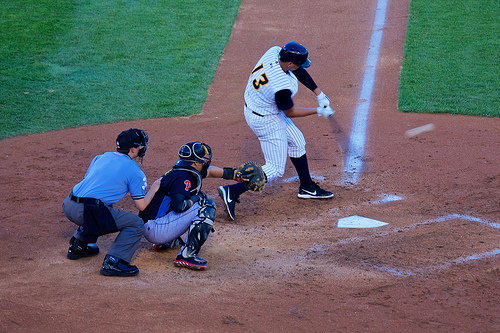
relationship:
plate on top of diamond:
[337, 211, 381, 232] [351, 15, 499, 215]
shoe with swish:
[298, 183, 332, 202] [303, 188, 319, 197]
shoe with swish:
[219, 181, 236, 218] [227, 186, 232, 203]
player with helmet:
[235, 32, 323, 203] [278, 39, 311, 68]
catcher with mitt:
[144, 141, 217, 266] [232, 161, 268, 190]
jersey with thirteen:
[247, 51, 291, 116] [252, 66, 268, 92]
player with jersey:
[235, 32, 323, 203] [247, 51, 291, 116]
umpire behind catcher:
[60, 130, 153, 277] [144, 141, 217, 266]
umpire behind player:
[60, 130, 153, 277] [235, 32, 323, 203]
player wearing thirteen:
[235, 32, 323, 203] [252, 66, 268, 92]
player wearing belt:
[235, 32, 323, 203] [243, 102, 263, 120]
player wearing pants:
[235, 32, 323, 203] [240, 105, 300, 174]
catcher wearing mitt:
[144, 141, 217, 266] [232, 161, 268, 190]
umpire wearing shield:
[60, 130, 153, 277] [137, 130, 148, 158]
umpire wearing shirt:
[60, 130, 153, 277] [72, 156, 146, 205]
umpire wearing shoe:
[60, 130, 153, 277] [99, 258, 137, 275]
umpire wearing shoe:
[60, 130, 153, 277] [65, 237, 99, 258]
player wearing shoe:
[235, 32, 323, 203] [298, 183, 332, 202]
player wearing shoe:
[235, 32, 323, 203] [219, 181, 236, 218]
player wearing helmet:
[235, 32, 323, 203] [278, 39, 311, 68]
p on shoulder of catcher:
[183, 179, 193, 192] [144, 141, 217, 266]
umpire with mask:
[60, 130, 153, 277] [137, 130, 148, 158]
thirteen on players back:
[252, 66, 268, 92] [242, 47, 280, 113]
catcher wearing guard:
[144, 141, 217, 266] [191, 211, 209, 256]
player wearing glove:
[235, 32, 323, 203] [317, 94, 331, 108]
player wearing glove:
[235, 32, 323, 203] [317, 109, 333, 116]